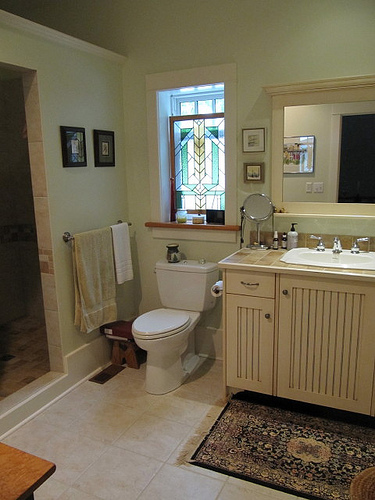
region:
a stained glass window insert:
[155, 115, 234, 214]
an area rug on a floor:
[176, 395, 373, 499]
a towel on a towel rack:
[67, 229, 118, 330]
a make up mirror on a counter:
[238, 195, 277, 249]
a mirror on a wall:
[273, 93, 372, 210]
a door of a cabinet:
[273, 275, 370, 414]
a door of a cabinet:
[223, 290, 276, 393]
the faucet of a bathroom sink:
[309, 229, 371, 255]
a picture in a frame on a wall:
[61, 124, 87, 169]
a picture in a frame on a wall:
[90, 125, 118, 170]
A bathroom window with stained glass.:
[169, 92, 226, 218]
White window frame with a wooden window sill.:
[142, 60, 240, 240]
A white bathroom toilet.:
[130, 255, 220, 393]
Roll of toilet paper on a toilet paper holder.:
[208, 281, 224, 299]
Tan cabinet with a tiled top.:
[216, 229, 374, 418]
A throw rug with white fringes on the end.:
[173, 395, 374, 498]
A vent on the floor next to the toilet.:
[89, 357, 123, 384]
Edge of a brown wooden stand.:
[0, 441, 55, 498]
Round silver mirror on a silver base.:
[241, 192, 272, 252]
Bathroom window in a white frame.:
[262, 73, 374, 235]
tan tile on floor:
[216, 478, 282, 499]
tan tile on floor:
[140, 455, 224, 497]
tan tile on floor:
[87, 443, 159, 495]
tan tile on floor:
[32, 426, 104, 479]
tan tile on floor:
[62, 477, 101, 498]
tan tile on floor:
[31, 471, 67, 497]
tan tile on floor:
[10, 415, 67, 457]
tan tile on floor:
[48, 389, 90, 429]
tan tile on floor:
[87, 395, 132, 442]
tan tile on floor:
[121, 402, 198, 465]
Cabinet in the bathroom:
[217, 246, 373, 416]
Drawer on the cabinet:
[223, 268, 276, 299]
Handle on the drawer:
[240, 279, 259, 287]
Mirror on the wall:
[280, 97, 373, 203]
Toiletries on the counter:
[272, 221, 298, 250]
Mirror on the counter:
[238, 191, 273, 248]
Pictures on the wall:
[57, 124, 265, 184]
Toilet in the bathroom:
[128, 256, 218, 391]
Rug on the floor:
[171, 395, 368, 494]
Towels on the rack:
[68, 221, 131, 332]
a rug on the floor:
[166, 399, 238, 484]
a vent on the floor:
[90, 371, 115, 388]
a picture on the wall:
[238, 119, 274, 156]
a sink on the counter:
[289, 238, 360, 278]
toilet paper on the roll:
[210, 270, 225, 302]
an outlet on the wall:
[302, 171, 332, 195]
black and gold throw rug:
[175, 392, 373, 498]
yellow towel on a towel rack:
[69, 226, 119, 332]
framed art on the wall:
[59, 123, 87, 166]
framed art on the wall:
[92, 127, 115, 166]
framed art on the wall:
[243, 161, 263, 183]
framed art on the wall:
[242, 126, 266, 154]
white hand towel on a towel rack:
[111, 221, 135, 282]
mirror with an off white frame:
[258, 72, 373, 218]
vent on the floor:
[88, 361, 125, 385]